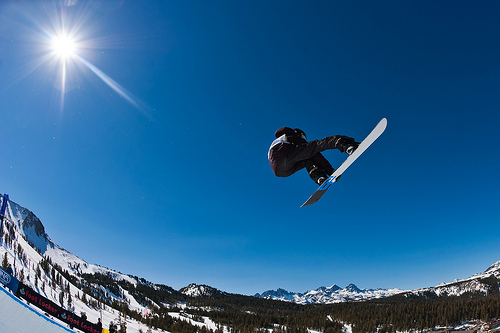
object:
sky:
[0, 0, 499, 297]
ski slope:
[0, 208, 142, 333]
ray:
[17, 3, 160, 130]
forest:
[0, 219, 500, 333]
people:
[79, 311, 86, 319]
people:
[96, 318, 102, 327]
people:
[108, 320, 118, 332]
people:
[120, 322, 127, 331]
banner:
[0, 269, 109, 333]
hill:
[0, 193, 500, 333]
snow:
[1, 192, 233, 331]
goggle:
[294, 128, 306, 140]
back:
[289, 134, 356, 164]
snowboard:
[299, 118, 387, 208]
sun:
[48, 33, 79, 59]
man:
[268, 127, 361, 186]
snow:
[303, 290, 405, 297]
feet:
[345, 140, 358, 155]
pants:
[276, 135, 354, 183]